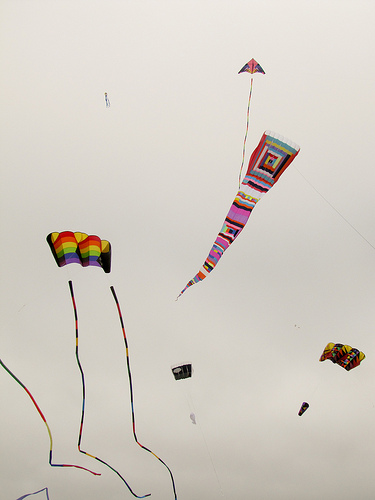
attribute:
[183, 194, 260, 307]
tail — conical, long, rainbow, striped, cone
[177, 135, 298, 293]
kite — bright, pink, square, triangular, orange, blue, multicolored, colorful, triangle, floating, beautiful, flying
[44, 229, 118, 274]
kite — square, rainbow, colorful, on left, floating, beautiful, flying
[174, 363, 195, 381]
kite — black, white, colorful, floating, small, flying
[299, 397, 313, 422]
windsock — small, black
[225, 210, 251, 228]
stripe — pink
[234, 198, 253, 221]
stripe — purple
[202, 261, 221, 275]
stripe — black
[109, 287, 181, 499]
tail — multicolored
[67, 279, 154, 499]
tail — multicolored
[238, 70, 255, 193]
strings — white, large, thin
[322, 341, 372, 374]
kite — colorful, small, psycodelic, floating, beautiful, flying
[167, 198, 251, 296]
pattern — tribal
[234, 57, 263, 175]
lantern — floating, white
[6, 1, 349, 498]
clouds — grey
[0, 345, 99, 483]
ribbon — blue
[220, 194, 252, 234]
color — pink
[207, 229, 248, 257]
color — green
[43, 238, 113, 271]
stripes — rainbow